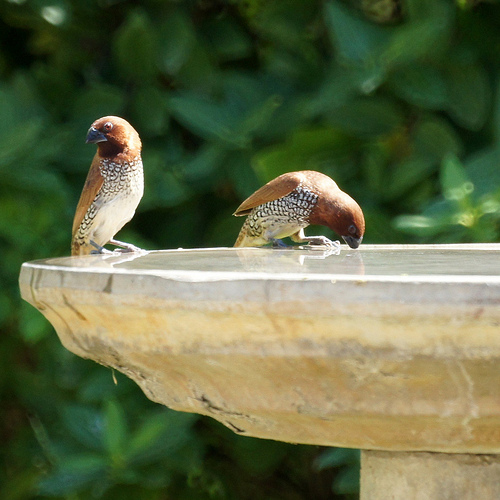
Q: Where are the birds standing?
A: On the fountain.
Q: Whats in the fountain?
A: Water.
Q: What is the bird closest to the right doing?
A: Drinking water.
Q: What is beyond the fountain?
A: Trees.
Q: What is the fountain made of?
A: Concrete.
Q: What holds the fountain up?
A: The post.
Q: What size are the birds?
A: Small.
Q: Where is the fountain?
A: Its outdoors.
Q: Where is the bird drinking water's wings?
A: On its back.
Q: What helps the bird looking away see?
A: His eye.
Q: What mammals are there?
A: Birds.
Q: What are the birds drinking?
A: Water.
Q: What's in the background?
A: Trees.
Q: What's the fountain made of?
A: Stone.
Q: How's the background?
A: Blurry.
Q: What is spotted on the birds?
A: Torsos.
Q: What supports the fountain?
A: Stand.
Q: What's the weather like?
A: Sunny.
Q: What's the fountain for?
A: Bird bath.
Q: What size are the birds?
A: Small.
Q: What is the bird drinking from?
A: A bird bath.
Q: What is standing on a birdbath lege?
A: Two birds.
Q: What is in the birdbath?
A: Water.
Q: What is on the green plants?
A: Leaves.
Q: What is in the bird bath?
A: Water.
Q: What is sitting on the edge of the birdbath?
A: A bird.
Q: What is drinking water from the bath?
A: A bird.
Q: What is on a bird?
A: Brown wings.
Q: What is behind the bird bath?
A: Green bushes.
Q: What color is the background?
A: Green.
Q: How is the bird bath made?
A: Stone.